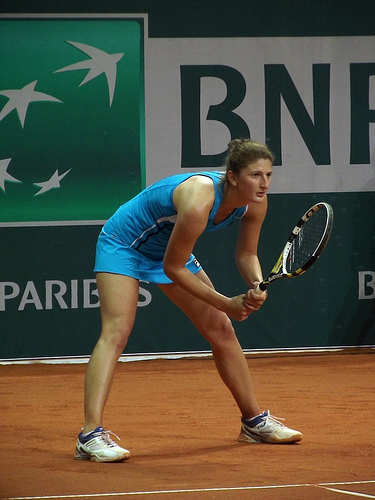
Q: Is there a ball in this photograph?
A: No, there are no balls.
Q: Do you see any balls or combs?
A: No, there are no balls or combs.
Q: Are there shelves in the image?
A: No, there are no shelves.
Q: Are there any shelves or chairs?
A: No, there are no shelves or chairs.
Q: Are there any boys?
A: No, there are no boys.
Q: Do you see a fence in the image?
A: No, there are no fences.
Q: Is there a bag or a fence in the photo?
A: No, there are no fences or bags.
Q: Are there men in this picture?
A: No, there are no men.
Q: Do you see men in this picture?
A: No, there are no men.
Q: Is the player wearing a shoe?
A: Yes, the player is wearing a shoe.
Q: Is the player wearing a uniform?
A: No, the player is wearing a shoe.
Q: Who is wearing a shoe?
A: The player is wearing a shoe.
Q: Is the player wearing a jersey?
A: No, the player is wearing a shoe.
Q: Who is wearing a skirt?
A: The player is wearing a skirt.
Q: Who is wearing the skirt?
A: The player is wearing a skirt.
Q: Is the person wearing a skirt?
A: Yes, the player is wearing a skirt.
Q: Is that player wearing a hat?
A: No, the player is wearing a skirt.